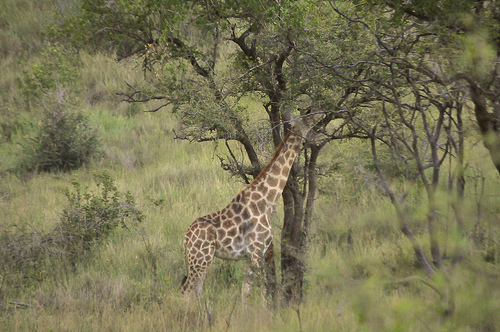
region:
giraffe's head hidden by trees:
[252, 73, 364, 148]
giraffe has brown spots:
[145, 102, 317, 275]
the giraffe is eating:
[227, 93, 392, 214]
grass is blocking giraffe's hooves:
[168, 252, 295, 322]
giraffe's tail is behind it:
[166, 255, 204, 293]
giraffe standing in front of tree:
[140, 49, 383, 329]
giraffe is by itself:
[17, 16, 352, 297]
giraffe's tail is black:
[165, 257, 202, 294]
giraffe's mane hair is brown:
[229, 115, 299, 194]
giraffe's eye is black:
[296, 94, 318, 124]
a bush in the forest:
[25, 91, 98, 181]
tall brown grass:
[5, 280, 150, 327]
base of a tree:
[275, 240, 310, 315]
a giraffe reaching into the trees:
[165, 80, 347, 305]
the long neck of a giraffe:
[246, 130, 306, 210]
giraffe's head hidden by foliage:
[290, 95, 335, 132]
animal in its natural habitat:
[95, 66, 395, 313]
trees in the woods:
[246, 46, 493, 111]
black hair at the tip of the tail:
[170, 211, 191, 291]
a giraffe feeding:
[27, 50, 430, 320]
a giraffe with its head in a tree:
[185, 105, 327, 297]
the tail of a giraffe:
[180, 233, 189, 293]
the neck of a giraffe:
[257, 131, 300, 207]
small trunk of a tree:
[261, 188, 314, 298]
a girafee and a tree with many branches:
[87, 1, 444, 311]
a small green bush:
[0, 165, 145, 295]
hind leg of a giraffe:
[187, 226, 212, 303]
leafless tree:
[365, 113, 473, 313]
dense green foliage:
[0, 1, 498, 112]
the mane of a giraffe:
[240, 133, 290, 190]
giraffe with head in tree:
[151, 105, 344, 306]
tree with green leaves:
[96, 1, 446, 142]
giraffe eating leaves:
[142, 38, 367, 325]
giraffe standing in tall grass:
[148, 94, 353, 329]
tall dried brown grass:
[100, 254, 310, 324]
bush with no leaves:
[18, 95, 105, 187]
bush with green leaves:
[16, 178, 168, 257]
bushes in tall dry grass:
[15, 108, 151, 270]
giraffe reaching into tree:
[132, 20, 342, 310]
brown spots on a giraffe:
[197, 212, 247, 245]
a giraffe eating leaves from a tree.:
[168, 77, 352, 329]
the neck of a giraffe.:
[256, 141, 309, 200]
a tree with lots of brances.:
[143, 30, 450, 312]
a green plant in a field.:
[26, 77, 138, 182]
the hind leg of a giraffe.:
[182, 246, 204, 313]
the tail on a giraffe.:
[174, 226, 196, 296]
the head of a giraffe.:
[278, 78, 361, 156]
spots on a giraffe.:
[245, 215, 260, 244]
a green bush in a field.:
[0, 106, 130, 190]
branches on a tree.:
[377, 24, 477, 139]